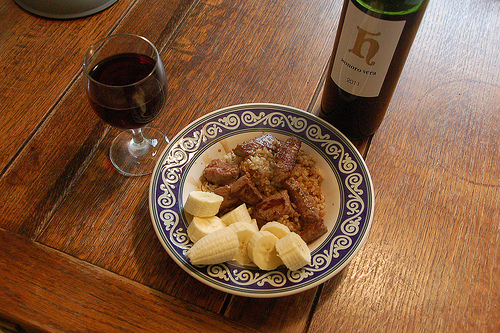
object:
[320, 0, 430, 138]
wine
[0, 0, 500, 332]
table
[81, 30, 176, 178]
glass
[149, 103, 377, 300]
bowl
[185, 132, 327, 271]
food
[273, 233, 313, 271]
banana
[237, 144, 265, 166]
rice and meat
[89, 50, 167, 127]
wine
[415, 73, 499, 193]
ring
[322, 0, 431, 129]
bottle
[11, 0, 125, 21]
pot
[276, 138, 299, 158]
meat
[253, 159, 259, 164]
rice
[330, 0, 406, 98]
label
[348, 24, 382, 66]
h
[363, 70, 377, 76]
words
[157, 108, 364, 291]
design